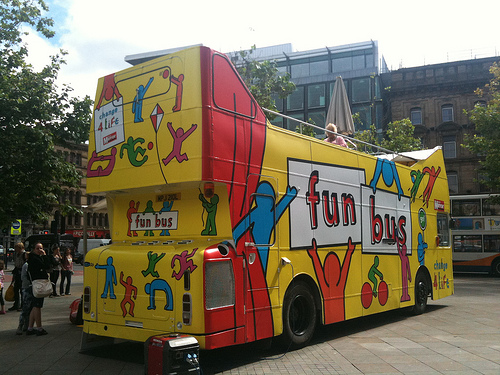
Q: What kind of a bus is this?
A: Fun bus.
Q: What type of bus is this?
A: Double decker.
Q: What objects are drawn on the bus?
A: Colorful people.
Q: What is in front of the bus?
A: Buildings.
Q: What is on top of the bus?
A: Closed umbrella.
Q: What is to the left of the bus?
A: Tree.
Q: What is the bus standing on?
A: Stone paved street.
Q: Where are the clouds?
A: In the sky.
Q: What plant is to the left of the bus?
A: A tree.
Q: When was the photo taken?
A: Daytime.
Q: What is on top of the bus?
A: Person.